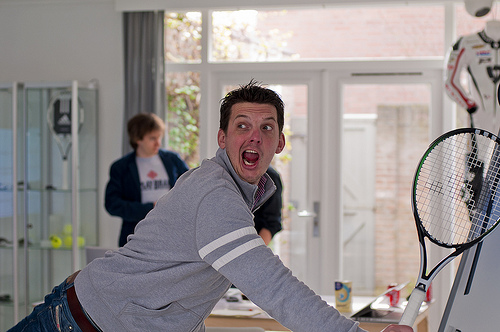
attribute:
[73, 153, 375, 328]
shirt — gray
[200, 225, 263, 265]
stripes — white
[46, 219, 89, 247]
tennis balls — stacked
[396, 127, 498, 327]
tennis racket — black and white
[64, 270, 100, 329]
belt — brown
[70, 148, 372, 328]
t shirt — gray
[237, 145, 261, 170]
mouth — wide open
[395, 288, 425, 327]
grip — white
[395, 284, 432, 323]
handle — white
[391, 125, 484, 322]
racket — tennis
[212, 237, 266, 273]
stripe — white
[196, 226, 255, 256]
stripe — white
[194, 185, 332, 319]
sleeve — grey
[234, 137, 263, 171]
mouth — man's, open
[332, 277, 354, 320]
container — yellow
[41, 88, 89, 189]
racket — tennis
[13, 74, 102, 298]
case — glass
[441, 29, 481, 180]
outfit — white, race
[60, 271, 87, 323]
belt — man's, brown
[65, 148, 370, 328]
jacket — grey, zippered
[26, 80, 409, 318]
man — brunette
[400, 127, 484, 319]
racket — tennis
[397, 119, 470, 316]
racket — tennis, white, black